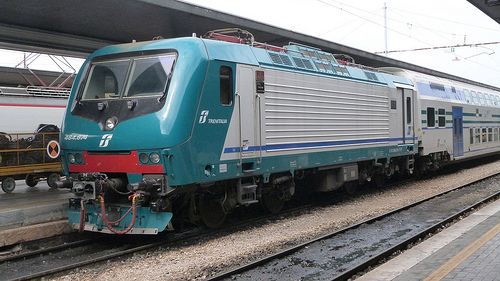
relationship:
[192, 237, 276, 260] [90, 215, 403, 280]
gravel between tracks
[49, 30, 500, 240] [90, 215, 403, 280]
railing on tracks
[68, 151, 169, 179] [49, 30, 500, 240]
bumper on railing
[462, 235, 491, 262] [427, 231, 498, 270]
stripe on ground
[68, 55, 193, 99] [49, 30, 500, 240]
windshield of railing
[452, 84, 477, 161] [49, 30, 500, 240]
door on railing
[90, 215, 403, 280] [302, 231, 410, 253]
tracks has water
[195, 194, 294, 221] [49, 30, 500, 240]
wheels on railing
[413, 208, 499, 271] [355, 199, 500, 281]
line on ground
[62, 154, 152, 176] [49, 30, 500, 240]
panel on railing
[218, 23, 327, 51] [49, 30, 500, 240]
handles top of railing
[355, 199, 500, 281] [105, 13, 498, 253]
ground has station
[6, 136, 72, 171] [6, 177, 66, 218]
cart on platform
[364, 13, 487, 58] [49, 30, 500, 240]
wires above railing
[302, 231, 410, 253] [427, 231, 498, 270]
water on ground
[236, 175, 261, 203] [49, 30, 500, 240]
steps on railing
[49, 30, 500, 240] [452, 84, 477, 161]
railing has door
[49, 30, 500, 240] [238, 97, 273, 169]
railing has railing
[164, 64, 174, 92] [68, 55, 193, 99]
wiper on windshield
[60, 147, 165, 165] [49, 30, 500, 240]
headlights on railing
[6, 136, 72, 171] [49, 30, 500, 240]
cart by railing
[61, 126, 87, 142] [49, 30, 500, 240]
number on railing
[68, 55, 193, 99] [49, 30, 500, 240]
windshield on railing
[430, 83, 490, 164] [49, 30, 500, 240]
car on railing